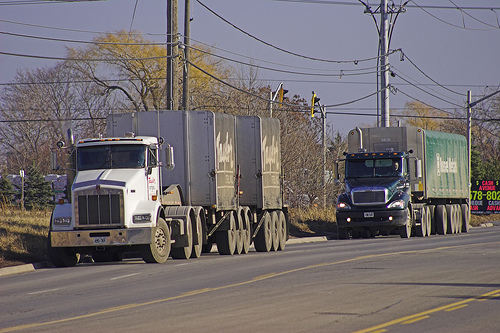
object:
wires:
[397, 49, 471, 94]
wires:
[201, 3, 377, 64]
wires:
[189, 61, 377, 115]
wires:
[5, 27, 159, 55]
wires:
[1, 76, 168, 87]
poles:
[379, 0, 390, 126]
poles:
[181, 0, 191, 112]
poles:
[319, 104, 326, 208]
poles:
[466, 89, 472, 222]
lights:
[388, 216, 392, 221]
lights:
[394, 153, 398, 156]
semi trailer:
[334, 126, 471, 239]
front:
[48, 135, 160, 251]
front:
[334, 150, 410, 226]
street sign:
[279, 87, 288, 107]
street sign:
[310, 93, 317, 117]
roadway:
[5, 271, 497, 331]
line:
[358, 290, 500, 333]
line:
[0, 245, 456, 333]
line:
[444, 303, 468, 311]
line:
[477, 294, 499, 302]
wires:
[387, 86, 456, 114]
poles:
[165, 0, 176, 111]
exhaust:
[67, 128, 76, 178]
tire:
[140, 216, 172, 263]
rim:
[155, 229, 166, 254]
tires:
[190, 214, 202, 258]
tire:
[172, 215, 193, 259]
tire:
[414, 208, 426, 238]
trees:
[19, 37, 149, 123]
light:
[133, 215, 150, 222]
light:
[347, 217, 352, 222]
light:
[388, 199, 405, 209]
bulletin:
[470, 180, 500, 214]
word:
[482, 180, 494, 185]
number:
[473, 191, 478, 201]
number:
[477, 191, 482, 200]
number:
[487, 191, 492, 201]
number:
[491, 191, 496, 201]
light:
[338, 203, 348, 209]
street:
[7, 224, 499, 331]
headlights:
[54, 218, 70, 225]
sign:
[471, 180, 500, 215]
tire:
[398, 207, 411, 238]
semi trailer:
[48, 109, 288, 267]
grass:
[2, 206, 484, 265]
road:
[0, 223, 498, 330]